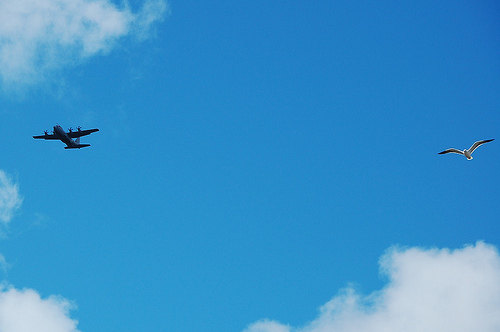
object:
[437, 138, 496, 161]
seagull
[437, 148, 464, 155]
wing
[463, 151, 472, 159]
body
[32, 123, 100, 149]
airplane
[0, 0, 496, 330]
sky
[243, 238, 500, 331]
cloud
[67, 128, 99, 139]
wing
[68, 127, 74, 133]
prop engine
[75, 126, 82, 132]
prop engine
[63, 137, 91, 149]
tail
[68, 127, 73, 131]
propeller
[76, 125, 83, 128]
propeller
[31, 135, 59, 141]
wing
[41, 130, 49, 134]
propeller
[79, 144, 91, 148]
wing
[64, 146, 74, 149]
wing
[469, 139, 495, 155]
wing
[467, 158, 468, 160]
tail feathers